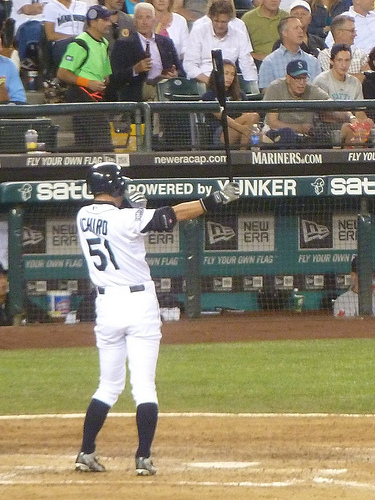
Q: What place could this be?
A: It is a field.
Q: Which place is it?
A: It is a field.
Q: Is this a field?
A: Yes, it is a field.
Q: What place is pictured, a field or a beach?
A: It is a field.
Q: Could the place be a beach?
A: No, it is a field.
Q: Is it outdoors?
A: Yes, it is outdoors.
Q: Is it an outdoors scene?
A: Yes, it is outdoors.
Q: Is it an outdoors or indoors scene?
A: It is outdoors.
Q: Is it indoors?
A: No, it is outdoors.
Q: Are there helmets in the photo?
A: Yes, there is a helmet.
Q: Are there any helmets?
A: Yes, there is a helmet.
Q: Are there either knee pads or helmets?
A: Yes, there is a helmet.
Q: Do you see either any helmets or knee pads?
A: Yes, there is a helmet.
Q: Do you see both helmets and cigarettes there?
A: No, there is a helmet but no cigarettes.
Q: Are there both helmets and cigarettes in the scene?
A: No, there is a helmet but no cigarettes.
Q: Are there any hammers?
A: No, there are no hammers.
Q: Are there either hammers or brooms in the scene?
A: No, there are no hammers or brooms.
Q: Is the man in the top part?
A: Yes, the man is in the top of the image.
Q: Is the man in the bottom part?
A: No, the man is in the top of the image.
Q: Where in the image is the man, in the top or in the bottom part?
A: The man is in the top of the image.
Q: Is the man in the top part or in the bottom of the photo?
A: The man is in the top of the image.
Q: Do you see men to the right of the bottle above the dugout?
A: Yes, there is a man to the right of the bottle.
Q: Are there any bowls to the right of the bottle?
A: No, there is a man to the right of the bottle.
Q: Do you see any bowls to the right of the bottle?
A: No, there is a man to the right of the bottle.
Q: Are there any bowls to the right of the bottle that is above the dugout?
A: No, there is a man to the right of the bottle.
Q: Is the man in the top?
A: Yes, the man is in the top of the image.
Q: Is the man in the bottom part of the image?
A: No, the man is in the top of the image.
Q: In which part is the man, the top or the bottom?
A: The man is in the top of the image.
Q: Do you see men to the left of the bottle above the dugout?
A: Yes, there is a man to the left of the bottle.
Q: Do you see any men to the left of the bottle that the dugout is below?
A: Yes, there is a man to the left of the bottle.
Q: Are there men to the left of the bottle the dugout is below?
A: Yes, there is a man to the left of the bottle.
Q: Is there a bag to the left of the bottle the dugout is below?
A: No, there is a man to the left of the bottle.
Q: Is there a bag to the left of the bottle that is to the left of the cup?
A: No, there is a man to the left of the bottle.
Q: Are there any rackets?
A: No, there are no rackets.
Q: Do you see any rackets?
A: No, there are no rackets.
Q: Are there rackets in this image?
A: No, there are no rackets.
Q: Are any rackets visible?
A: No, there are no rackets.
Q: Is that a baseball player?
A: Yes, that is a baseball player.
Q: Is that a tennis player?
A: No, that is a baseball player.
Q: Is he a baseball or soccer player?
A: That is a baseball player.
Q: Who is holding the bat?
A: The player is holding the bat.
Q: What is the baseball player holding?
A: The player is holding the bat.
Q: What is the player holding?
A: The player is holding the bat.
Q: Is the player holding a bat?
A: Yes, the player is holding a bat.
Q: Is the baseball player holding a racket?
A: No, the player is holding a bat.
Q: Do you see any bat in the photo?
A: Yes, there is a bat.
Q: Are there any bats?
A: Yes, there is a bat.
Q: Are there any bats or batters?
A: Yes, there is a bat.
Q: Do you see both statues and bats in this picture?
A: No, there is a bat but no statues.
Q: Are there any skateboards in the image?
A: No, there are no skateboards.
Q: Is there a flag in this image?
A: No, there are no flags.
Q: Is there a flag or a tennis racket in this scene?
A: No, there are no flags or rackets.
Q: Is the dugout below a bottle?
A: Yes, the dugout is below a bottle.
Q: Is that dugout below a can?
A: No, the dugout is below a bottle.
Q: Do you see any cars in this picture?
A: No, there are no cars.